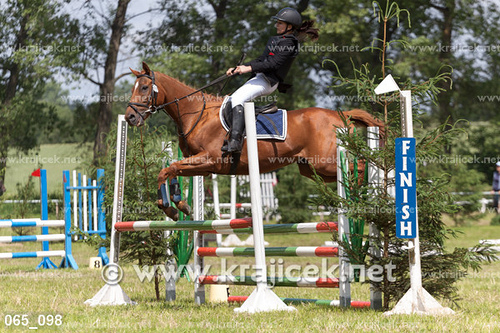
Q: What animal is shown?
A: A horse.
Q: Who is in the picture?
A: A man.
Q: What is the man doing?
A: Competing.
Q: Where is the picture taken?
A: An equestrian field.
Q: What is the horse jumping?
A: Poles.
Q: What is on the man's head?
A: A helmet.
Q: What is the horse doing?
A: Jumping over fence.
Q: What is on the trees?
A: Green leaves.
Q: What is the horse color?
A: Brown.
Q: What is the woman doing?
A: Leaning back.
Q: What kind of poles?
A: The poles are striped.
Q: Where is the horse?
A: In the air.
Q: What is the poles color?
A: Green red and white.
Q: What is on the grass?
A: Blue and white poles.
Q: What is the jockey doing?
A: Jumping with a hurdle.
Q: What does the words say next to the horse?
A: Finish.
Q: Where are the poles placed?
A: On grass.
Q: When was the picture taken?
A: Daytime.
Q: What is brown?
A: Horse.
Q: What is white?
A: Poles.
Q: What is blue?
A: Fence.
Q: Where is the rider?
A: On the horse.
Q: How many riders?
A: One.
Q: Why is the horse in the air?
A: Jumping.